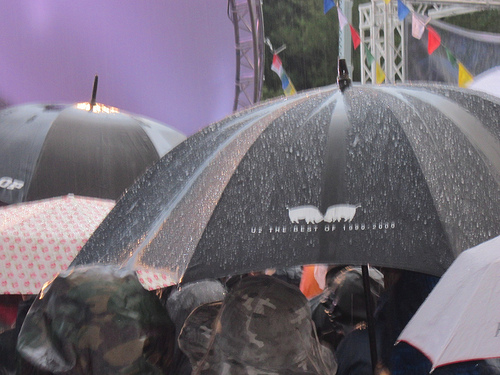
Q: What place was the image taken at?
A: It was taken at the stage.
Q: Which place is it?
A: It is a stage.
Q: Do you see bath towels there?
A: No, there are no bath towels.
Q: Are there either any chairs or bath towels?
A: No, there are no bath towels or chairs.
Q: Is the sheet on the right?
A: Yes, the sheet is on the right of the image.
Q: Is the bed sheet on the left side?
A: No, the bed sheet is on the right of the image.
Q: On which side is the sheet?
A: The sheet is on the right of the image.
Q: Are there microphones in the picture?
A: No, there are no microphones.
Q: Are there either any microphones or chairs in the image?
A: No, there are no microphones or chairs.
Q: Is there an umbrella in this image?
A: Yes, there is an umbrella.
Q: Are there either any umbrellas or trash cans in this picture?
A: Yes, there is an umbrella.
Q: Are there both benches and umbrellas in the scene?
A: No, there is an umbrella but no benches.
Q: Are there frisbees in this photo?
A: No, there are no frisbees.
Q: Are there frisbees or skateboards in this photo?
A: No, there are no frisbees or skateboards.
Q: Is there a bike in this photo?
A: No, there are no bikes.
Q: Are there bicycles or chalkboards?
A: No, there are no bicycles or chalkboards.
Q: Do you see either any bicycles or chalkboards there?
A: No, there are no bicycles or chalkboards.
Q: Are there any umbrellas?
A: Yes, there is an umbrella.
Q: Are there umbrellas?
A: Yes, there is an umbrella.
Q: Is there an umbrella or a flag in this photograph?
A: Yes, there is an umbrella.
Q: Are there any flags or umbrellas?
A: Yes, there is an umbrella.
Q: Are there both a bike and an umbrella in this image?
A: No, there is an umbrella but no bikes.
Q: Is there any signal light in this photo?
A: No, there are no traffic lights.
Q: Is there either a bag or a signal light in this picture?
A: No, there are no traffic lights or bags.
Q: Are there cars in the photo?
A: No, there are no cars.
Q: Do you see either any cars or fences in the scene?
A: No, there are no cars or fences.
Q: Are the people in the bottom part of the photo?
A: Yes, the people are in the bottom of the image.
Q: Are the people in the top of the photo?
A: No, the people are in the bottom of the image.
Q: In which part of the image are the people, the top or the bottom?
A: The people are in the bottom of the image.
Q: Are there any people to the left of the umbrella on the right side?
A: Yes, there are people to the left of the umbrella.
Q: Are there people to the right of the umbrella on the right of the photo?
A: No, the people are to the left of the umbrella.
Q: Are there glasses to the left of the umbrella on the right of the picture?
A: No, there are people to the left of the umbrella.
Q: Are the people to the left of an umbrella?
A: Yes, the people are to the left of an umbrella.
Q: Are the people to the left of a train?
A: No, the people are to the left of an umbrella.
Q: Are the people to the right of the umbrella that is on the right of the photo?
A: No, the people are to the left of the umbrella.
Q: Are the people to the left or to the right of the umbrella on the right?
A: The people are to the left of the umbrella.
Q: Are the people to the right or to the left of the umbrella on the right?
A: The people are to the left of the umbrella.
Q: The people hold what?
A: The people hold the umbrella.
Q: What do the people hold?
A: The people hold the umbrella.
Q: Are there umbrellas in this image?
A: Yes, there is an umbrella.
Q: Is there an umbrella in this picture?
A: Yes, there is an umbrella.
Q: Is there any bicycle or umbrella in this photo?
A: Yes, there is an umbrella.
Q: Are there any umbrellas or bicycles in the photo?
A: Yes, there is an umbrella.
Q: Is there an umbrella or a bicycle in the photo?
A: Yes, there is an umbrella.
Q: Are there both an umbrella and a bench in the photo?
A: No, there is an umbrella but no benches.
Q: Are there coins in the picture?
A: No, there are no coins.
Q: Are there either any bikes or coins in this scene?
A: No, there are no coins or bikes.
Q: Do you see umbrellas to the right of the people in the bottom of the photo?
A: Yes, there is an umbrella to the right of the people.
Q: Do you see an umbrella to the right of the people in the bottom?
A: Yes, there is an umbrella to the right of the people.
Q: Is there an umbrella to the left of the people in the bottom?
A: No, the umbrella is to the right of the people.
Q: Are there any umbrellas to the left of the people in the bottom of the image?
A: No, the umbrella is to the right of the people.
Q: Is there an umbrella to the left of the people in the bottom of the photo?
A: No, the umbrella is to the right of the people.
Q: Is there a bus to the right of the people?
A: No, there is an umbrella to the right of the people.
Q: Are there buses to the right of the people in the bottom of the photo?
A: No, there is an umbrella to the right of the people.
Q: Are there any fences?
A: No, there are no fences.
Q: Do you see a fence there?
A: No, there are no fences.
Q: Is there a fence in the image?
A: No, there are no fences.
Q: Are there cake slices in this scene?
A: No, there are no cake slices.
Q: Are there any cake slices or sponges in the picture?
A: No, there are no cake slices or sponges.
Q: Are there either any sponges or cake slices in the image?
A: No, there are no cake slices or sponges.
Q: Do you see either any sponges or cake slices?
A: No, there are no cake slices or sponges.